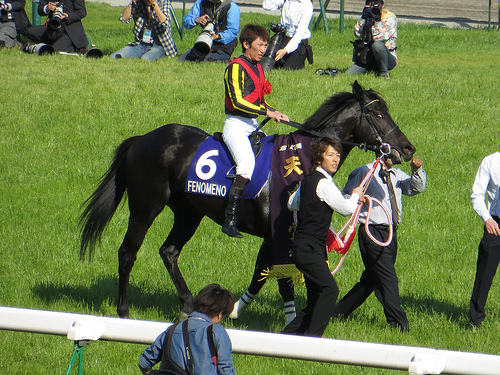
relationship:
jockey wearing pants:
[217, 18, 274, 245] [220, 114, 263, 176]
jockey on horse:
[217, 18, 274, 245] [75, 80, 422, 322]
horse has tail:
[75, 80, 422, 322] [78, 142, 123, 267]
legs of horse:
[113, 193, 203, 318] [75, 80, 422, 322]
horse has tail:
[75, 80, 422, 322] [69, 132, 157, 269]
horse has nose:
[75, 80, 422, 322] [380, 120, 423, 158]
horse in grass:
[75, 80, 422, 322] [19, 285, 489, 374]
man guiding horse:
[284, 137, 368, 337] [75, 80, 422, 322]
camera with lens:
[355, 3, 383, 28] [369, 5, 381, 18]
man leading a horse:
[284, 137, 368, 337] [75, 80, 422, 322]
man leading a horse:
[330, 150, 421, 339] [75, 80, 422, 322]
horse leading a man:
[75, 80, 422, 322] [284, 137, 368, 337]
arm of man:
[225, 60, 284, 122] [218, 21, 288, 245]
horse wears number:
[75, 80, 422, 322] [193, 146, 220, 180]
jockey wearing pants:
[217, 18, 274, 245] [210, 96, 288, 240]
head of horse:
[323, 80, 420, 184] [74, 80, 469, 366]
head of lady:
[306, 131, 350, 178] [224, 32, 375, 261]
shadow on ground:
[214, 272, 420, 322] [48, 31, 483, 336]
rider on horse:
[221, 27, 286, 233] [347, 72, 427, 167]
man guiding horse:
[330, 150, 421, 339] [75, 80, 422, 322]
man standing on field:
[463, 137, 498, 329] [2, 1, 497, 372]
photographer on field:
[312, 0, 402, 83] [2, 1, 497, 372]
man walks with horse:
[284, 137, 368, 337] [75, 80, 422, 322]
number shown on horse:
[195, 149, 220, 180] [75, 80, 422, 322]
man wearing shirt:
[141, 277, 241, 373] [135, 308, 237, 373]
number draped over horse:
[195, 149, 220, 180] [75, 80, 422, 322]